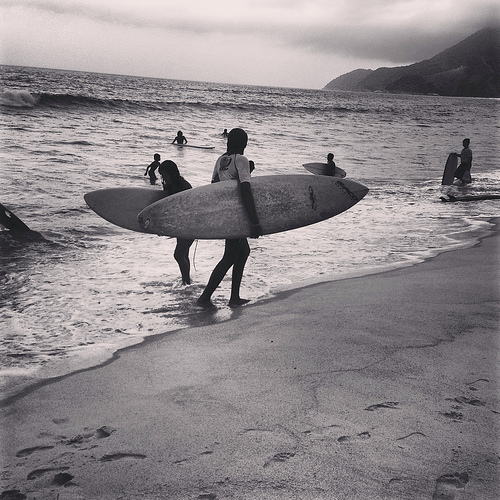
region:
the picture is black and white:
[10, 23, 482, 484]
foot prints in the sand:
[271, 363, 494, 486]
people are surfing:
[100, 110, 400, 322]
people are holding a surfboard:
[125, 110, 380, 297]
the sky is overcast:
[50, 0, 435, 106]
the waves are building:
[0, 60, 405, 137]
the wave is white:
[2, 80, 62, 120]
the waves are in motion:
[5, 65, 390, 140]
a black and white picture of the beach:
[18, 122, 498, 483]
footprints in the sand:
[18, 431, 139, 497]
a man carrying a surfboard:
[186, 130, 329, 335]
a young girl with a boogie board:
[436, 136, 491, 226]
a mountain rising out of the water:
[312, 41, 457, 117]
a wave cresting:
[8, 75, 128, 138]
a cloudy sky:
[162, 17, 245, 59]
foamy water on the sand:
[14, 283, 181, 395]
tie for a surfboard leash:
[134, 213, 164, 238]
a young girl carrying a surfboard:
[133, 158, 211, 301]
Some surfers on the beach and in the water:
[0, 113, 499, 316]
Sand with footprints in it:
[6, 301, 490, 494]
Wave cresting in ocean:
[0, 75, 406, 140]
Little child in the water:
[139, 150, 167, 184]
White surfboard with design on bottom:
[134, 165, 390, 245]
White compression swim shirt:
[197, 146, 254, 202]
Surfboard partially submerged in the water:
[0, 205, 55, 260]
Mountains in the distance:
[318, 33, 495, 108]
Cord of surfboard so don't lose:
[186, 232, 201, 280]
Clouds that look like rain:
[2, 0, 497, 97]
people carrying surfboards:
[78, 145, 370, 308]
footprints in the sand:
[11, 381, 477, 487]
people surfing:
[146, 106, 246, 148]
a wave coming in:
[0, 85, 410, 117]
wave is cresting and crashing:
[0, 86, 98, 111]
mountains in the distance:
[321, 20, 496, 91]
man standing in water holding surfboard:
[435, 131, 477, 186]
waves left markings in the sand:
[251, 283, 497, 379]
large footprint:
[435, 459, 472, 496]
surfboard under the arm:
[123, 174, 372, 249]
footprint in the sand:
[428, 468, 475, 498]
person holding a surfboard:
[297, 143, 352, 180]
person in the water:
[135, 143, 168, 188]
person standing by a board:
[167, 127, 218, 154]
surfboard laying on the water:
[171, 139, 218, 151]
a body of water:
[0, 63, 498, 430]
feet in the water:
[191, 285, 258, 310]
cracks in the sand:
[289, 333, 426, 406]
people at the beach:
[1, 90, 496, 347]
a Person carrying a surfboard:
[191, 121, 271, 328]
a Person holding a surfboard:
[434, 134, 479, 195]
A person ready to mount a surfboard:
[168, 124, 216, 151]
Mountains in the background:
[323, 21, 493, 94]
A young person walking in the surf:
[141, 149, 162, 184]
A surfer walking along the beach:
[195, 124, 271, 319]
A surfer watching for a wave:
[440, 128, 476, 195]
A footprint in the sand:
[424, 466, 471, 496]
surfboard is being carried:
[135, 170, 369, 240]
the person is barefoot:
[196, 128, 262, 307]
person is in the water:
[170, 127, 215, 152]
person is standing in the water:
[440, 136, 472, 186]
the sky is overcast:
[0, 0, 499, 86]